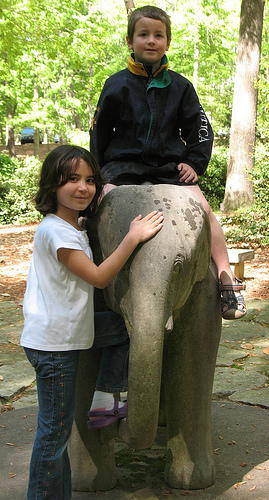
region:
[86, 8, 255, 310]
child sitting on an elephant statute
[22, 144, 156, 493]
young girl standing next to elephant statute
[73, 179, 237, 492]
gray elephant statute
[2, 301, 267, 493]
broken pavement around the elephant statute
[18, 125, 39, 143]
car parked in the lot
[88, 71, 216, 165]
coat young boy is wearing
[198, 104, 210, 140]
white lettering on black coat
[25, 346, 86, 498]
blue jeans young girl is wearing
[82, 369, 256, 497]
shadows on the pavement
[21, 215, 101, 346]
white shirt the girl is wearing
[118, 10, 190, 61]
head of a person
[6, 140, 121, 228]
head of a person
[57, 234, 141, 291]
arm of a person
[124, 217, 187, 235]
hand of a person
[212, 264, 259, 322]
feet of a person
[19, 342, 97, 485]
leg of a person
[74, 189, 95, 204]
mouth of a person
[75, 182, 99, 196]
nose of a person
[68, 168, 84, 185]
eye of a person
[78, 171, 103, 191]
eye of a person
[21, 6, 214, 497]
boy and girl with a baby elephant statue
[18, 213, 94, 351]
white top little girl is wearing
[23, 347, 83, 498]
girl is wearing blue jeans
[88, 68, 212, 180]
black jacket boy is wearing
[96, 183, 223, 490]
sitting on the ground is an elephant statue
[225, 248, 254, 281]
concrete bench in back of the elephant and children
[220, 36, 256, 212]
tall trunk of a tree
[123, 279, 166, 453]
trunk of the elephant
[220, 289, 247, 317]
left shoe of the boy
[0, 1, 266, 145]
tall trees in the background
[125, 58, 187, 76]
collar on the boy's jacket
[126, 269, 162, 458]
trunk on the elephant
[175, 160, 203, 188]
left hand on boy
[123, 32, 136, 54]
right ear on boy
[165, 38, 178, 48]
left ear on boy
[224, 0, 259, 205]
bark of the tree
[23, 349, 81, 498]
jeans on the girl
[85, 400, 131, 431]
purple sandles on foot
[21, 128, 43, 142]
car in the background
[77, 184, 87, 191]
the little girl's nose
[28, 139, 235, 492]
girl standing next to a statue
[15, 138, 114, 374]
girl wearing a white blouse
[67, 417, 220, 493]
hoofs on a cement elephant statue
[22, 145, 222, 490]
girl standing next to an elephant statue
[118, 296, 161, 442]
elephant trunk made of cement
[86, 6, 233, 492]
kid sitting on an elephant statue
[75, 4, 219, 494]
boy sitting on an elephant statue made of cement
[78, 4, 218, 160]
young boy wearing a jacket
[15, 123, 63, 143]
cars parked behind trees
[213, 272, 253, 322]
sandal on a small foot